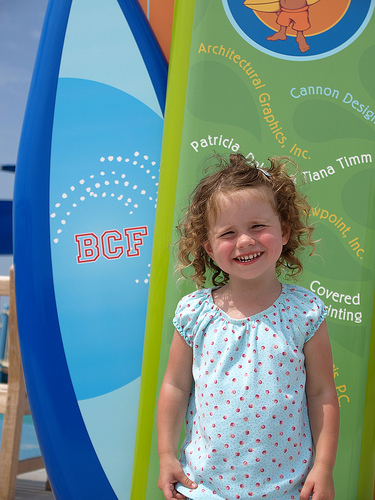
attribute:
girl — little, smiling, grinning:
[157, 149, 341, 499]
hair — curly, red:
[170, 147, 325, 294]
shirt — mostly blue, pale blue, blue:
[172, 282, 330, 499]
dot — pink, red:
[244, 429, 250, 435]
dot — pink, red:
[278, 474, 284, 480]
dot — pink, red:
[222, 325, 227, 331]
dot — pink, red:
[304, 320, 311, 328]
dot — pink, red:
[209, 464, 217, 472]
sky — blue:
[2, 1, 52, 165]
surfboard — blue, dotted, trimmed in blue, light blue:
[13, 1, 168, 498]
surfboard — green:
[127, 1, 374, 499]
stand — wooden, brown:
[0, 264, 52, 499]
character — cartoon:
[242, 1, 352, 54]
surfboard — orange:
[139, 1, 173, 67]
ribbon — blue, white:
[256, 166, 271, 180]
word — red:
[76, 227, 149, 265]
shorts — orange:
[276, 5, 312, 32]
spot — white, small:
[107, 155, 116, 163]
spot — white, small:
[140, 190, 145, 197]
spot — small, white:
[50, 212, 58, 219]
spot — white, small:
[70, 186, 77, 193]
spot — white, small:
[133, 151, 139, 156]